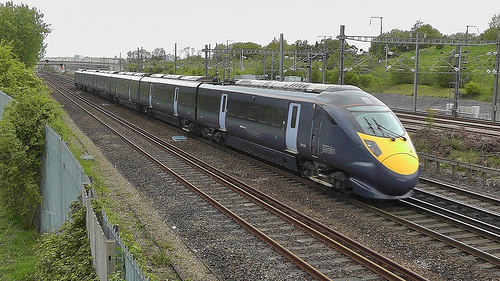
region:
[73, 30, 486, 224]
a train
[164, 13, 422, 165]
a train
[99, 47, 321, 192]
a train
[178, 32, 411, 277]
a train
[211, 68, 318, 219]
a train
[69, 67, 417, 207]
a train on the tracks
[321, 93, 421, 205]
the engineer section of a train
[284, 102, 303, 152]
a door on a train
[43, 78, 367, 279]
train tracks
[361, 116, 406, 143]
the windshield wipers on the front of a train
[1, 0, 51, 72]
a green tree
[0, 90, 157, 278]
a wooden fence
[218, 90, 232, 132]
a door on a train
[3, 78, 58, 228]
a shrub climbing a wooden fence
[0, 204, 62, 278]
a patch of grass on the side of the train tracks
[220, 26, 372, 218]
a train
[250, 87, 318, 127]
a train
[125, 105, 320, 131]
a train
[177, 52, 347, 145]
a train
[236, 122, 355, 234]
a train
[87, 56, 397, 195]
train is dark blue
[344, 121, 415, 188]
yellow face on train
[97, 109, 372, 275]
train tracks are brown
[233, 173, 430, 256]
gravel next to tracks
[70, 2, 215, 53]
sky is grey and overcast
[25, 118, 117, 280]
grey fence next to train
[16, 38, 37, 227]
green trees next to tracks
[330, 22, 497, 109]
power lines next to train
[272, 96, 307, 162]
white doors on train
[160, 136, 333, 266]
train ties are grey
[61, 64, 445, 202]
The train is long.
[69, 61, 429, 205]
The train is black and yellow.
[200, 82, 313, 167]
The train doors are gray.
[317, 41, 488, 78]
The trees are green.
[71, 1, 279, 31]
The sky is white.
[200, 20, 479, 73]
Power lines are in the picture.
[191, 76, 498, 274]
Several sets of tracks are in the picture.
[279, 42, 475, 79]
Trees are in the background.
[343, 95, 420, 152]
The train has a window in it.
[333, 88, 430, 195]
The front of the train is yellow.